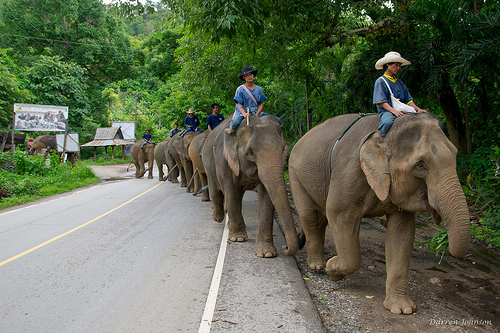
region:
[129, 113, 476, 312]
Six elephants are walking in a row.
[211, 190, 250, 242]
Two feet straddling a white line.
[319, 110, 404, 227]
The elephant has a strap on its back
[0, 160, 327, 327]
The road is paved and has a yellow line.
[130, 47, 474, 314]
Six people on six elephants.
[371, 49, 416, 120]
The man is wearing a white hat.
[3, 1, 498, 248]
The trees and brush have green leaves.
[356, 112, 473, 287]
The elephant looks old and tired.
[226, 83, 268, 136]
A person is wearing a blue suit.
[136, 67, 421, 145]
Six people are wearing blue clothes.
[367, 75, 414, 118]
THE MAN IS WEARING A BLUE SHIRT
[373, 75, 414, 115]
THE MAN HAS A WHITE BAG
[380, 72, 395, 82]
THE MAN IS WEARING A YELLOW BANDANA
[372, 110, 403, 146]
THE MAN IS WEARING JEANS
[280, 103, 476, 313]
THE ELEPHANT IS IN THE FRONT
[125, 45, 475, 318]
THE PEOPLE ARE RIDING IN A LINE OF ASIAN ELEPHANTS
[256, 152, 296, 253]
THE ASIAN ELEPHANT HAS A LONG TRUNK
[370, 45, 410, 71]
THE MAN IS WEARING A WHITE HAT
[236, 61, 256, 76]
THE MAN IS WEARING A BLUE HAT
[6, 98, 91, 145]
THE SIGN IS BIG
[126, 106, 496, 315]
Six elephants walking in a row down street.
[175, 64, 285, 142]
Men riding on backs of elephants.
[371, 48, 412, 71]
Man wearing white hat on head.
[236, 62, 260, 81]
Man wearing black hat on head.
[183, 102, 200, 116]
Man wearing tan hat on head.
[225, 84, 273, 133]
Man dressed in blue shirt and pants.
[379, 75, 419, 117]
Man carrying white bag over shoulder.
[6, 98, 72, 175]
Sign standing on side of road.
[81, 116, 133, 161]
Tin roof structure on side of road.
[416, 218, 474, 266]
Elephant holding grass in trunk.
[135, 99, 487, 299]
Numerous men riding elephants.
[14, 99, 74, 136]
A large sign in the background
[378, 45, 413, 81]
A man wearing a hat.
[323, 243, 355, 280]
An elephant with a foot up.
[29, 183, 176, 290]
A yellow line in the road.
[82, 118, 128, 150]
A metal roof in the back.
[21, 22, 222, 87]
Trees and forest in the background.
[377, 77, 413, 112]
A satchel around the man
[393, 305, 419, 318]
The toes of the elephant.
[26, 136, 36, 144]
A stop sign in the background.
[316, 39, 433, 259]
a man riding an elephant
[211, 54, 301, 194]
a man riding an elephant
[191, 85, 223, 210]
a man riding an elephant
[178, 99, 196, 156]
a man riding an elephant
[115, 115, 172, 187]
a man riding an elephant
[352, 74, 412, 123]
the shirt is blue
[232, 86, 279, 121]
the shirt is blue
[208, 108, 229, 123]
the shirt is blue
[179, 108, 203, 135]
the shirt is blue